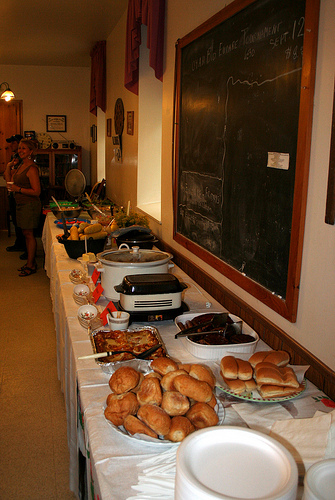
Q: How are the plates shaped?
A: Circular.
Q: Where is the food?
A: On the table.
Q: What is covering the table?
A: White tablecloth.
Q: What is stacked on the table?
A: Paper plates.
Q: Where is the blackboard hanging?
A: On the wall.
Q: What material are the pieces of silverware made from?
A: Plastic.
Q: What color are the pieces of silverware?
A: White.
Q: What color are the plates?
A: White.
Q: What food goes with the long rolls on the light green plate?
A: Hot dogs.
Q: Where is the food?
A: On the table.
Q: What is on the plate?
A: Bread.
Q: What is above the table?
A: A chalkboard.